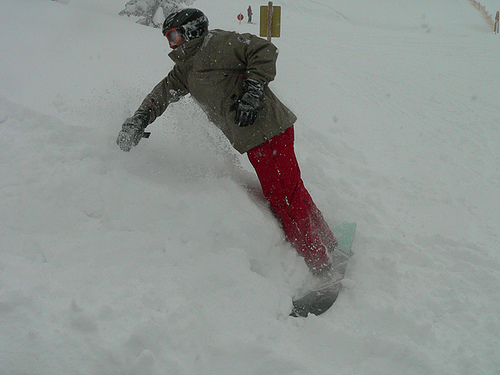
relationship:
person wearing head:
[117, 9, 356, 321] [160, 7, 209, 49]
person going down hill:
[117, 9, 356, 321] [1, 2, 496, 374]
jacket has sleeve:
[124, 30, 298, 153] [234, 28, 279, 83]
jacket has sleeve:
[124, 30, 298, 153] [135, 65, 189, 125]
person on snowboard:
[117, 9, 356, 321] [292, 223, 357, 315]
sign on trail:
[260, 4, 284, 37] [13, 1, 497, 368]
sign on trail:
[238, 13, 244, 21] [13, 1, 497, 368]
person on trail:
[117, 9, 356, 321] [13, 1, 497, 368]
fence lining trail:
[467, 2, 495, 32] [13, 1, 497, 368]